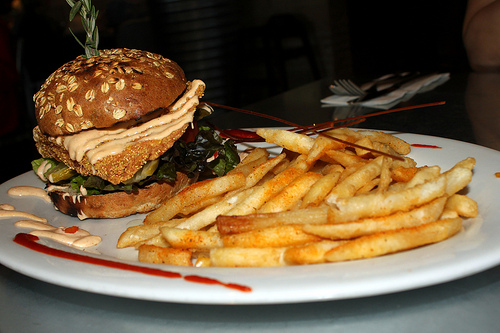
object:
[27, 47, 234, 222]
sandwich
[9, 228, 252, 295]
ketchup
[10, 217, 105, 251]
dressing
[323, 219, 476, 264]
fries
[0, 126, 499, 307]
plate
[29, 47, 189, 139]
bun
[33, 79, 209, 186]
meat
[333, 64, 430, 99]
fork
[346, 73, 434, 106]
knife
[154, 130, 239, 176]
lettuce